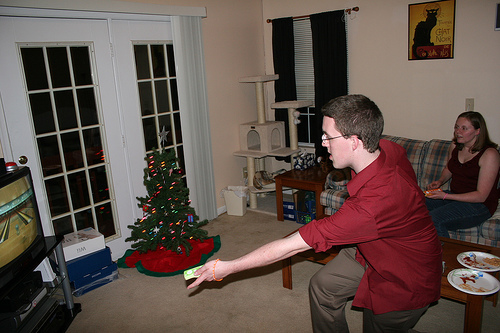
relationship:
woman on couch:
[434, 108, 496, 239] [317, 122, 494, 235]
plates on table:
[456, 248, 497, 296] [301, 224, 495, 315]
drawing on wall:
[403, 3, 465, 68] [347, 8, 468, 111]